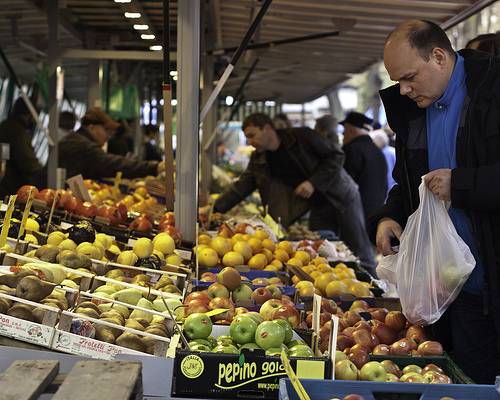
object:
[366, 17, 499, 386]
man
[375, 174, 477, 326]
bag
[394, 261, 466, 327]
fruit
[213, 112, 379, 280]
man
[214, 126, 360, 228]
jacket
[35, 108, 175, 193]
man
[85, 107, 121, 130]
brown cap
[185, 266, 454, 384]
apples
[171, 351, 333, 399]
writing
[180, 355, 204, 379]
circle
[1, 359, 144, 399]
pallet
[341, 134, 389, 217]
elderly man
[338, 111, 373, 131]
black hat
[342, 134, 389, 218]
black jacket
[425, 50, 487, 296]
shirt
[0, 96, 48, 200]
person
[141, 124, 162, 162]
person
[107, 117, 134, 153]
person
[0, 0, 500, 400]
market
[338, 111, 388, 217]
person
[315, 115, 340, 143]
person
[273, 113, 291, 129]
person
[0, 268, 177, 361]
shelf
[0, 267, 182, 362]
pears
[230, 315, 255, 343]
green apple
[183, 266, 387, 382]
red and yellow apple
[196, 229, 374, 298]
oranges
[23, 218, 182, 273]
lemon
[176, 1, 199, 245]
pole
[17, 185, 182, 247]
peppers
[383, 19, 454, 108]
head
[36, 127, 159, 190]
jacket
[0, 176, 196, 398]
box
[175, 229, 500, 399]
box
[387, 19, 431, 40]
bald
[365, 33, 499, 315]
coat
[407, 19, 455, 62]
dark hair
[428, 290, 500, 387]
pants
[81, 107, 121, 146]
head